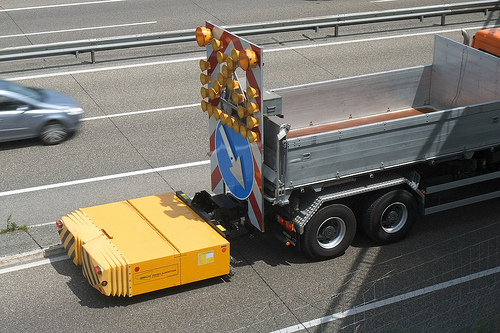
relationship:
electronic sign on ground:
[56, 191, 231, 303] [1, 0, 498, 330]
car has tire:
[3, 69, 83, 145] [29, 104, 96, 163]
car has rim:
[3, 69, 83, 145] [45, 124, 65, 147]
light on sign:
[194, 26, 258, 144] [177, 7, 287, 245]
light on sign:
[193, 28, 255, 153] [192, 36, 306, 173]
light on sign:
[194, 26, 258, 144] [196, 20, 271, 227]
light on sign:
[194, 26, 258, 144] [193, 17, 268, 235]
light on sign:
[194, 26, 258, 144] [192, 16, 271, 149]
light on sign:
[194, 26, 258, 144] [197, 18, 263, 209]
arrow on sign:
[213, 122, 248, 194] [193, 17, 268, 235]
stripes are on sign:
[203, 125, 264, 228] [193, 17, 268, 235]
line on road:
[1, 159, 207, 194] [0, 0, 500, 332]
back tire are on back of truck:
[296, 202, 358, 261] [175, 14, 487, 250]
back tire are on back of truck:
[355, 188, 421, 245] [175, 14, 487, 250]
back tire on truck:
[364, 185, 421, 247] [192, 0, 497, 262]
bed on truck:
[257, 35, 494, 205] [202, 20, 497, 260]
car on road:
[0, 79, 84, 146] [0, 0, 500, 332]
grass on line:
[0, 215, 27, 235] [1, 220, 61, 232]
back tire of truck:
[296, 202, 358, 261] [196, 35, 471, 264]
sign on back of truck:
[193, 17, 268, 235] [202, 20, 497, 260]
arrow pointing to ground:
[219, 124, 246, 190] [1, 0, 498, 330]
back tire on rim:
[296, 202, 358, 261] [316, 216, 346, 249]